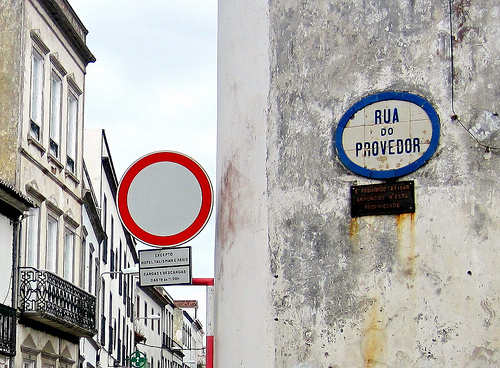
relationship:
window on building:
[43, 197, 63, 276] [0, 0, 96, 366]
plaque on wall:
[320, 82, 435, 177] [202, 75, 498, 368]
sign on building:
[124, 341, 151, 366] [33, 68, 225, 364]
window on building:
[34, 70, 82, 168] [6, 65, 132, 368]